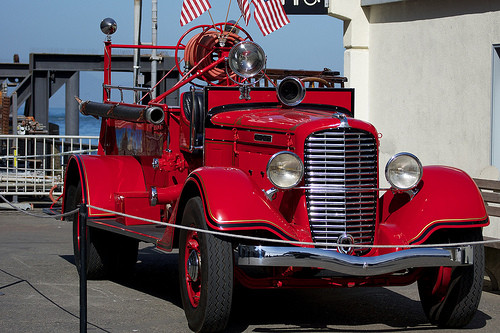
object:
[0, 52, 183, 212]
structure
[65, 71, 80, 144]
beam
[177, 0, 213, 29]
flag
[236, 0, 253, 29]
flag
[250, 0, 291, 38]
flag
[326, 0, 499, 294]
building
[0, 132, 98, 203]
white fence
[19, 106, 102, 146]
water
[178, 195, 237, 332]
tire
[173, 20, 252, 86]
wheel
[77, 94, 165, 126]
pole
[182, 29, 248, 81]
hose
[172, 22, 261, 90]
spool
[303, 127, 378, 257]
grill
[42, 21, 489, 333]
car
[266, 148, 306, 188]
light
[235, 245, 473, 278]
bumper